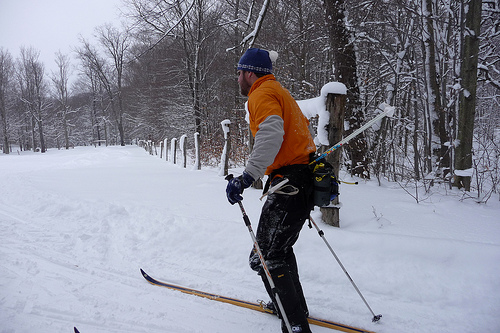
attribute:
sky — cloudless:
[0, 1, 255, 108]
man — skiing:
[225, 47, 319, 331]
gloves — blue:
[200, 158, 262, 210]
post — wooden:
[311, 82, 354, 127]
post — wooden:
[186, 119, 206, 180]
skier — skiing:
[186, 45, 370, 332]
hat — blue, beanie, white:
[238, 48, 273, 77]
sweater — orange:
[245, 77, 315, 174]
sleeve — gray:
[247, 117, 282, 183]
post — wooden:
[322, 79, 349, 223]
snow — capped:
[322, 80, 344, 96]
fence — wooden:
[125, 126, 353, 196]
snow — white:
[112, 148, 469, 313]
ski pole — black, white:
[230, 175, 300, 333]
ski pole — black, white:
[305, 216, 390, 321]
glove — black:
[226, 175, 253, 202]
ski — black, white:
[139, 261, 367, 333]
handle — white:
[267, 177, 293, 196]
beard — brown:
[239, 74, 251, 96]